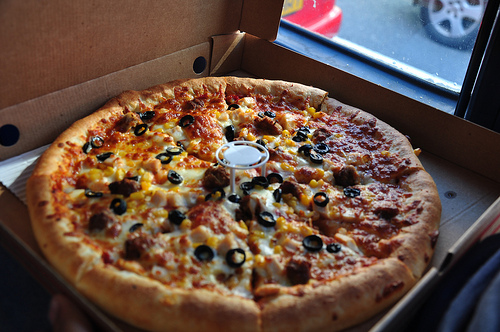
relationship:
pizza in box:
[23, 75, 444, 330] [7, 4, 497, 174]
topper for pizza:
[227, 132, 286, 192] [23, 75, 444, 330]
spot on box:
[439, 189, 454, 201] [21, 38, 480, 324]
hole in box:
[186, 45, 219, 78] [21, 38, 480, 324]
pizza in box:
[40, 69, 445, 330] [21, 38, 480, 324]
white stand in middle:
[212, 139, 273, 192] [186, 127, 305, 203]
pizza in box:
[23, 75, 444, 330] [1, 2, 495, 330]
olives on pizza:
[80, 118, 346, 268] [40, 69, 445, 330]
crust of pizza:
[205, 70, 402, 147] [40, 69, 445, 330]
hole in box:
[0, 120, 23, 150] [12, 12, 189, 73]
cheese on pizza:
[152, 119, 337, 257] [40, 69, 445, 330]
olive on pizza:
[242, 176, 255, 193] [23, 75, 444, 330]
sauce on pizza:
[55, 144, 103, 191] [30, 44, 487, 326]